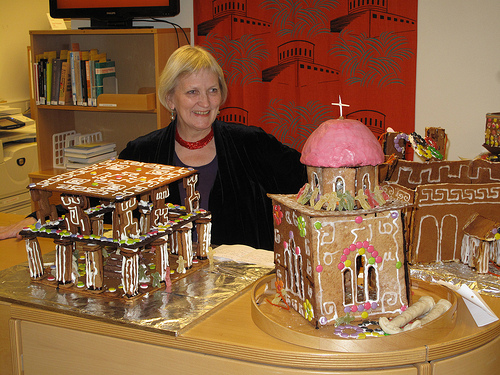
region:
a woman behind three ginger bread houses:
[15, 47, 489, 317]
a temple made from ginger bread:
[254, 95, 422, 329]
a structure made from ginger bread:
[13, 160, 215, 287]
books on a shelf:
[33, 51, 110, 107]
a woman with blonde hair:
[148, 40, 232, 130]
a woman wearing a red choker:
[151, 45, 238, 147]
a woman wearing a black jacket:
[113, 46, 297, 207]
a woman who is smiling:
[158, 33, 239, 134]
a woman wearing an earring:
[143, 65, 219, 137]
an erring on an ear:
[159, 95, 181, 125]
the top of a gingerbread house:
[301, 117, 385, 169]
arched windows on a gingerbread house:
[339, 254, 379, 307]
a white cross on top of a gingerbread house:
[331, 96, 349, 117]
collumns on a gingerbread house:
[18, 233, 139, 301]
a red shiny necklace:
[172, 128, 216, 151]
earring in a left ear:
[166, 103, 176, 122]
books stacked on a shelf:
[63, 140, 116, 169]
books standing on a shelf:
[31, 48, 119, 106]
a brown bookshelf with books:
[28, 27, 189, 169]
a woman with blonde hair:
[158, 45, 230, 131]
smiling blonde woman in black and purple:
[115, 44, 307, 251]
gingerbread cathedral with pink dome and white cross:
[266, 95, 410, 326]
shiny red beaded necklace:
[172, 123, 214, 151]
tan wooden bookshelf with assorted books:
[27, 28, 189, 182]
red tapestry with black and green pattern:
[190, 1, 415, 161]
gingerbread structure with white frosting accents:
[20, 158, 211, 302]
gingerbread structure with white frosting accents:
[377, 113, 499, 272]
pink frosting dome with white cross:
[297, 95, 384, 166]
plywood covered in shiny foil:
[0, 240, 272, 333]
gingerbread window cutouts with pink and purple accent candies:
[337, 240, 382, 312]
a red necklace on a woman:
[171, 126, 215, 151]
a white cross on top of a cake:
[331, 93, 348, 120]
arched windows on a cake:
[335, 248, 385, 310]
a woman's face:
[166, 61, 221, 131]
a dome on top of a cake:
[296, 114, 386, 174]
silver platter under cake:
[138, 298, 190, 337]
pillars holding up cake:
[111, 243, 144, 300]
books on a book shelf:
[30, 50, 116, 107]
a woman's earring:
[162, 105, 179, 122]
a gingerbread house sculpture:
[261, 93, 421, 330]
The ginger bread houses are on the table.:
[50, 123, 496, 313]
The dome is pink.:
[293, 109, 392, 174]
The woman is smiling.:
[135, 44, 245, 130]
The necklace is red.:
[161, 123, 221, 146]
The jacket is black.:
[123, 126, 339, 265]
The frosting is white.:
[18, 138, 225, 323]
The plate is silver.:
[10, 244, 265, 342]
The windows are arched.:
[329, 239, 389, 312]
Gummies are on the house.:
[300, 184, 410, 225]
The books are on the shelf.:
[18, 45, 138, 116]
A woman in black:
[118, 76, 245, 247]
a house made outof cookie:
[260, 118, 415, 326]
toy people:
[136, 245, 191, 292]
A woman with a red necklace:
[153, 98, 239, 166]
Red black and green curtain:
[258, 19, 388, 135]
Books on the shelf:
[29, 25, 169, 181]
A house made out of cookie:
[15, 158, 189, 309]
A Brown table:
[187, 295, 252, 371]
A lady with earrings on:
[161, 82, 222, 132]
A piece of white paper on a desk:
[433, 268, 483, 345]